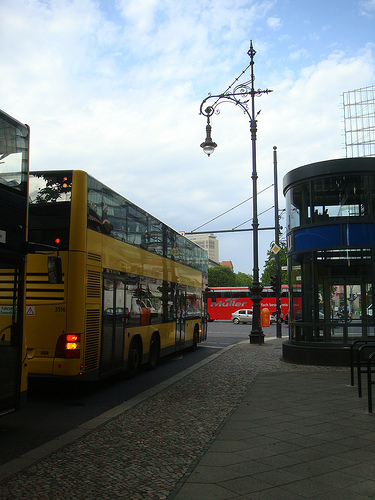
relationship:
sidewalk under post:
[2, 332, 373, 499] [272, 144, 283, 338]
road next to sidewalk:
[0, 318, 291, 466] [2, 332, 373, 499]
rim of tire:
[130, 346, 141, 367] [125, 344, 143, 379]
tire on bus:
[147, 339, 160, 372] [29, 170, 207, 384]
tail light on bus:
[66, 332, 80, 352] [29, 170, 207, 384]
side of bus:
[82, 174, 209, 381] [29, 170, 207, 384]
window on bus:
[87, 175, 163, 259] [29, 170, 207, 384]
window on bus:
[128, 203, 146, 247] [29, 170, 207, 384]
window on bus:
[148, 215, 164, 253] [29, 170, 207, 384]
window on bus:
[165, 226, 186, 262] [29, 170, 207, 384]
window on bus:
[127, 281, 139, 323] [29, 170, 207, 384]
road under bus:
[0, 318, 291, 466] [29, 170, 207, 384]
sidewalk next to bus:
[2, 332, 373, 499] [29, 170, 207, 384]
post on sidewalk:
[244, 40, 265, 346] [2, 332, 373, 499]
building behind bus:
[177, 231, 221, 263] [29, 170, 207, 384]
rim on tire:
[151, 343, 159, 361] [147, 339, 160, 372]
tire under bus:
[147, 339, 160, 372] [29, 170, 207, 384]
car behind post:
[230, 306, 254, 326] [244, 40, 265, 346]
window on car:
[238, 309, 246, 317] [230, 306, 254, 326]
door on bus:
[100, 275, 126, 376] [29, 170, 207, 384]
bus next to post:
[29, 170, 207, 384] [244, 40, 265, 346]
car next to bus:
[230, 306, 254, 326] [205, 283, 299, 323]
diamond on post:
[271, 244, 281, 255] [272, 144, 283, 338]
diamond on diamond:
[272, 245, 279, 253] [271, 244, 281, 255]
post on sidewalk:
[272, 144, 283, 338] [2, 332, 373, 499]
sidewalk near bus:
[2, 332, 373, 499] [29, 170, 207, 384]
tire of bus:
[125, 344, 143, 379] [29, 170, 207, 384]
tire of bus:
[147, 339, 160, 372] [29, 170, 207, 384]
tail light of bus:
[66, 332, 80, 352] [29, 170, 207, 384]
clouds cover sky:
[3, 1, 375, 270] [0, 0, 375, 281]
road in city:
[0, 318, 291, 466] [0, 2, 374, 499]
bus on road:
[29, 170, 207, 384] [0, 318, 291, 466]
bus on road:
[205, 283, 299, 323] [0, 318, 291, 466]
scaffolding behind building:
[340, 83, 374, 157] [282, 155, 375, 362]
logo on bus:
[210, 298, 251, 310] [205, 283, 299, 323]